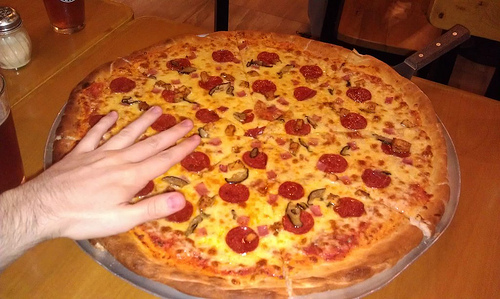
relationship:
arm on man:
[6, 110, 206, 297] [1, 104, 204, 271]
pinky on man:
[77, 104, 122, 149] [18, 122, 151, 257]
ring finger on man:
[106, 103, 166, 150] [4, 106, 200, 295]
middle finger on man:
[132, 113, 202, 151] [4, 102, 204, 243]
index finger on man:
[139, 131, 200, 174] [1, 104, 204, 271]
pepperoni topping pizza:
[335, 104, 370, 132] [52, 29, 450, 297]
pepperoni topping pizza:
[277, 181, 306, 199] [52, 29, 450, 297]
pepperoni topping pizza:
[195, 104, 220, 124] [52, 29, 450, 297]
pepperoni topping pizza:
[195, 67, 225, 91] [52, 29, 450, 297]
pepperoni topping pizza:
[227, 223, 258, 254] [52, 29, 450, 297]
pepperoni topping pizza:
[274, 195, 314, 237] [26, 16, 462, 289]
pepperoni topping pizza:
[273, 107, 317, 143] [26, 16, 462, 289]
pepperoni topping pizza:
[101, 70, 137, 97] [26, 16, 462, 289]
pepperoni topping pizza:
[351, 160, 398, 195] [26, 16, 462, 289]